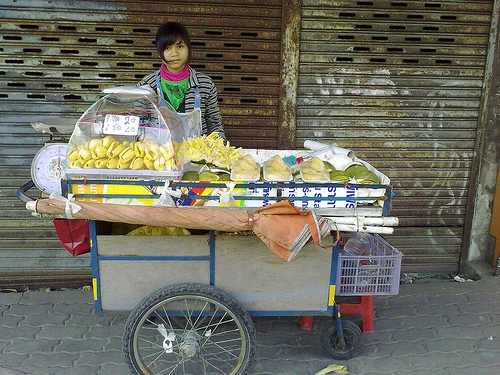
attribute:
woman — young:
[144, 20, 227, 141]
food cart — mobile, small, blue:
[18, 88, 402, 374]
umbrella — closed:
[25, 200, 400, 263]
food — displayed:
[64, 130, 382, 186]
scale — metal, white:
[30, 141, 73, 200]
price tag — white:
[103, 113, 140, 135]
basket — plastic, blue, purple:
[341, 237, 401, 296]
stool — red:
[300, 275, 373, 332]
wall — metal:
[0, 0, 474, 271]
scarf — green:
[160, 63, 193, 111]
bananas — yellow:
[69, 135, 176, 171]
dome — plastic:
[67, 86, 185, 175]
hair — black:
[155, 21, 189, 63]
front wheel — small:
[322, 320, 363, 360]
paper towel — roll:
[305, 140, 355, 160]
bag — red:
[53, 217, 91, 256]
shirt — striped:
[140, 70, 226, 140]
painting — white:
[302, 70, 472, 250]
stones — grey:
[410, 316, 459, 351]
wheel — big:
[126, 281, 259, 373]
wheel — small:
[322, 320, 364, 362]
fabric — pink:
[160, 65, 191, 81]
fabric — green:
[163, 79, 187, 108]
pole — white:
[328, 213, 401, 236]